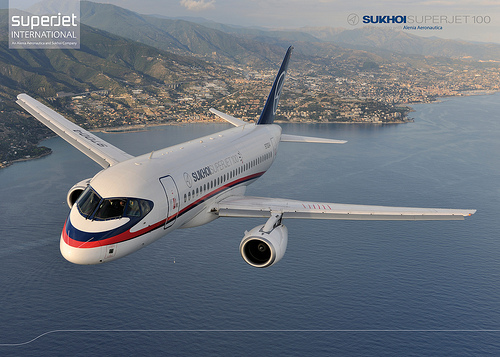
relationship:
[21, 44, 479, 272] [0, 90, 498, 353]
airplane flying over ocean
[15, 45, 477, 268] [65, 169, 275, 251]
plane with stripes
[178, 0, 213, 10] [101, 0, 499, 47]
clouds in sky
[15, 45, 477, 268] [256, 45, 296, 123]
plane has tail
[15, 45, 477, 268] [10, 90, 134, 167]
plane has large wing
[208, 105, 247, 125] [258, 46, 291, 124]
wing near tail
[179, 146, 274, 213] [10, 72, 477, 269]
windows on side of plane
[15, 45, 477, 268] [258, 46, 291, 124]
plane has tail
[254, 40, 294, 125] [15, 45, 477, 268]
tail fin of plane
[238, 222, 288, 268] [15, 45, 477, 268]
engine of plane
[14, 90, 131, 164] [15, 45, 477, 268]
wing of plane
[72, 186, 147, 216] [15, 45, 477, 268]
front window of plane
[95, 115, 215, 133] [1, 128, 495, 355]
shote line of ocean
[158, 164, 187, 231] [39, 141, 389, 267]
book on side of plane